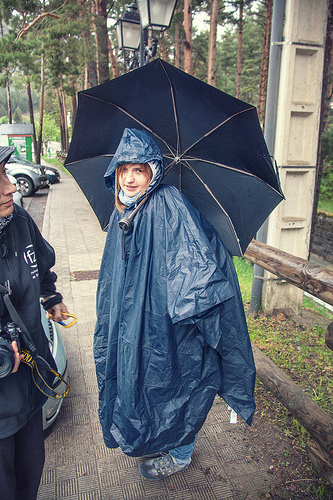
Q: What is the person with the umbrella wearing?
A: Rain poncho.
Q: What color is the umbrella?
A: Black.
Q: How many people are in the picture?
A: Two.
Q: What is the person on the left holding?
A: Camera.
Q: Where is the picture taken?
A: On the sidewalk.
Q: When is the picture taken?
A: Daytime.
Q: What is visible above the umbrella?
A: Street lights.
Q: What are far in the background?
A: Trees.